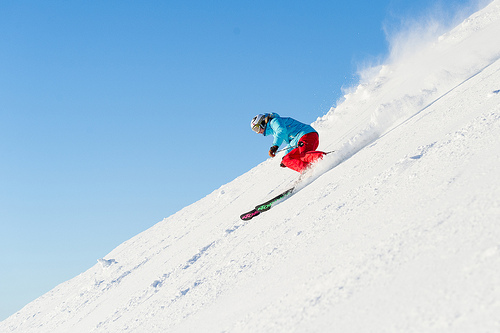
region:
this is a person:
[247, 109, 332, 189]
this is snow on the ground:
[109, 238, 199, 318]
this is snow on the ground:
[271, 221, 336, 286]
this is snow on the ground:
[344, 88, 424, 182]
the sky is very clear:
[109, 49, 211, 128]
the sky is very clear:
[254, 10, 322, 100]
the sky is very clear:
[44, 110, 113, 177]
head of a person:
[240, 110, 272, 140]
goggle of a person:
[248, 117, 260, 137]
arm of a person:
[268, 127, 294, 152]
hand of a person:
[266, 145, 287, 160]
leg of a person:
[277, 142, 314, 168]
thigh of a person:
[285, 132, 314, 162]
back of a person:
[272, 102, 310, 136]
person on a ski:
[203, 53, 374, 241]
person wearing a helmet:
[243, 93, 270, 145]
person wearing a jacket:
[223, 61, 383, 235]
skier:
[242, 102, 332, 203]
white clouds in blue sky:
[15, 29, 46, 64]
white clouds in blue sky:
[55, 59, 85, 106]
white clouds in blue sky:
[5, 102, 65, 146]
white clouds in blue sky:
[11, 121, 62, 165]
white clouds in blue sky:
[18, 183, 78, 234]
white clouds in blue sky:
[52, 38, 103, 93]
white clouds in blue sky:
[64, 136, 109, 166]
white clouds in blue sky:
[125, 26, 179, 74]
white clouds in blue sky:
[108, 91, 150, 126]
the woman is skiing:
[196, 78, 356, 223]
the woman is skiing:
[215, 80, 333, 225]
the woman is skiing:
[202, 100, 345, 235]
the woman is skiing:
[202, 90, 347, 233]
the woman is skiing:
[215, 87, 357, 255]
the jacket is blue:
[252, 110, 307, 147]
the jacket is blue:
[242, 113, 307, 153]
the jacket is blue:
[251, 110, 315, 167]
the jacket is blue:
[242, 111, 321, 164]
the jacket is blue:
[254, 110, 312, 150]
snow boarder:
[244, 101, 334, 201]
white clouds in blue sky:
[14, 16, 59, 66]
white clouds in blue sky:
[57, 131, 95, 168]